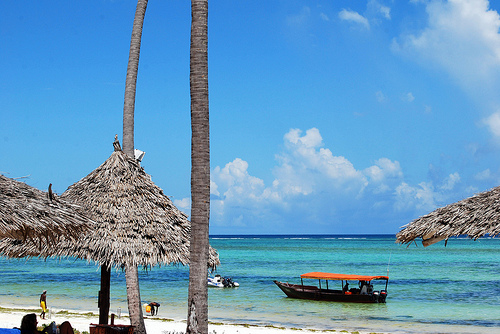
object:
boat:
[273, 270, 390, 303]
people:
[342, 283, 350, 295]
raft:
[208, 276, 240, 288]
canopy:
[0, 134, 222, 319]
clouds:
[172, 0, 499, 228]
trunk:
[122, 0, 149, 334]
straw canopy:
[395, 187, 499, 254]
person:
[148, 302, 161, 317]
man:
[39, 290, 47, 320]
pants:
[40, 301, 47, 313]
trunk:
[185, 0, 211, 334]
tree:
[185, 0, 210, 334]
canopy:
[300, 271, 389, 294]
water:
[0, 238, 500, 334]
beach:
[0, 300, 371, 334]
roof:
[0, 134, 220, 276]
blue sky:
[1, 0, 497, 236]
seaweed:
[0, 307, 378, 334]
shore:
[0, 297, 497, 334]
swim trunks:
[40, 301, 46, 313]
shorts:
[40, 301, 46, 313]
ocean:
[0, 233, 500, 334]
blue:
[139, 92, 189, 151]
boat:
[208, 276, 240, 287]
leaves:
[81, 170, 188, 252]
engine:
[217, 280, 221, 286]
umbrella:
[0, 133, 221, 277]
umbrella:
[0, 174, 99, 254]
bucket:
[146, 306, 152, 313]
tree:
[121, 0, 148, 334]